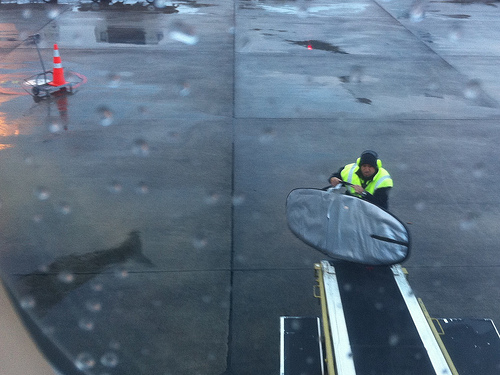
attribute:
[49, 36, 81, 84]
cone — wet, orange traffic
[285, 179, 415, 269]
bag — silver, oval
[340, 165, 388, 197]
vest — yellow safety 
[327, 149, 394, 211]
employee — airport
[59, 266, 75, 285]
circle — small 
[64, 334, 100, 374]
circle — small 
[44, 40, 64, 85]
traffic cone — orange, white traffic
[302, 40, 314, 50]
red light — red 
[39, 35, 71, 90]
cone — orange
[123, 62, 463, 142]
pavement — black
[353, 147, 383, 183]
head — man's 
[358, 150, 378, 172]
cap — knit, dark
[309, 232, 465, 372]
conveyor belt — black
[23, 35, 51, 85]
handle — black 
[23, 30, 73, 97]
hand cart — hand 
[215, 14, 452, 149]
pavement — wet, black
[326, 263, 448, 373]
conveyor belt — black conveyor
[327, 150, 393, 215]
worker — airport, male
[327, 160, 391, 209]
coat — black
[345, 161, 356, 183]
reflective stripe — reflective 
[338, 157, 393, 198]
safety vest — safety 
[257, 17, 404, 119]
paved area — ark wet paved 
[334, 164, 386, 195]
vest — yellow safety 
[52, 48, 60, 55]
stripe — gray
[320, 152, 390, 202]
vest — flourescent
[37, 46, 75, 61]
stripe — reflective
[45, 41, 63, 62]
stripe — reflective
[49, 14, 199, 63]
puddle — large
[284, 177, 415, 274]
circle — small 